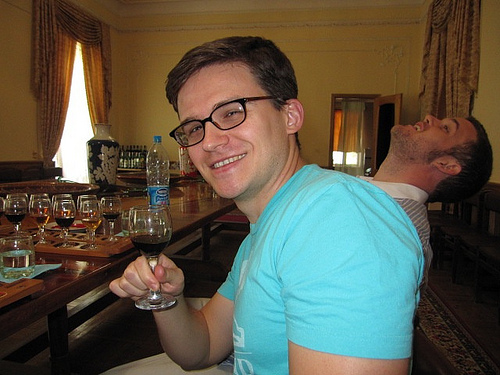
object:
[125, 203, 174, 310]
glass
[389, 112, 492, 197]
head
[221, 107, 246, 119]
eye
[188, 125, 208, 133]
eye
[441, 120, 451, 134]
eye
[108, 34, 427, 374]
man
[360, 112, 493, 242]
man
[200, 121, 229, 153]
nose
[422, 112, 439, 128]
nose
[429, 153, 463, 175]
ear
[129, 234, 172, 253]
wine